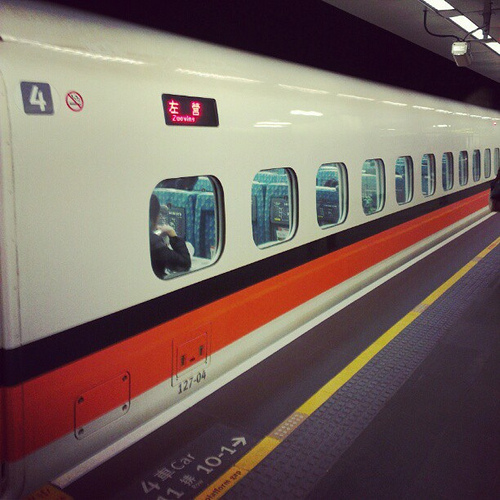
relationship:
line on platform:
[137, 227, 498, 498] [95, 225, 485, 496]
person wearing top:
[106, 197, 216, 277] [149, 232, 188, 275]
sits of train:
[250, 174, 295, 238] [6, 2, 498, 499]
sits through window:
[250, 174, 295, 238] [253, 168, 300, 254]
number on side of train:
[28, 85, 48, 113] [4, 2, 496, 438]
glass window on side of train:
[251, 167, 297, 250] [7, 47, 475, 458]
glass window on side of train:
[150, 176, 226, 281] [6, 2, 498, 499]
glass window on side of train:
[251, 167, 297, 250] [6, 2, 498, 499]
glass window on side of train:
[361, 159, 384, 216] [6, 2, 498, 499]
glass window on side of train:
[395, 156, 414, 207] [6, 2, 498, 499]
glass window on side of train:
[315, 162, 349, 229] [6, 2, 498, 499]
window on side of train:
[443, 152, 454, 190] [6, 2, 498, 499]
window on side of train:
[482, 147, 492, 177] [6, 2, 498, 499]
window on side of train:
[491, 146, 498, 173] [6, 2, 498, 499]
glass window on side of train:
[395, 156, 414, 207] [7, 47, 475, 458]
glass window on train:
[150, 176, 226, 281] [6, 2, 498, 499]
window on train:
[472, 149, 481, 182] [6, 2, 498, 499]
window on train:
[469, 146, 486, 185] [6, 2, 498, 499]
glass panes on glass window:
[149, 175, 221, 283] [150, 178, 222, 273]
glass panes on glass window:
[250, 166, 301, 248] [249, 159, 293, 242]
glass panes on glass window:
[312, 164, 352, 229] [309, 161, 347, 226]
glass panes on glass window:
[360, 155, 388, 215] [365, 154, 384, 213]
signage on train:
[158, 94, 218, 129] [6, 2, 498, 499]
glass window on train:
[251, 167, 297, 250] [6, 2, 498, 499]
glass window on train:
[315, 162, 349, 229] [6, 2, 498, 499]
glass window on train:
[361, 159, 384, 216] [6, 2, 498, 499]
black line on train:
[334, 317, 480, 386] [6, 2, 498, 499]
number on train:
[175, 359, 215, 404] [6, 2, 498, 499]